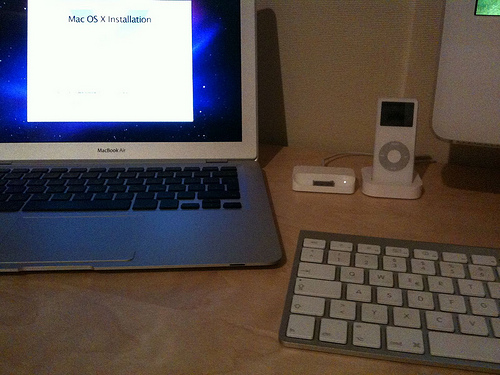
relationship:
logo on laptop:
[87, 139, 125, 164] [32, 33, 263, 260]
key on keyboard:
[321, 266, 424, 328] [305, 235, 484, 351]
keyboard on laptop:
[305, 235, 484, 351] [32, 33, 263, 260]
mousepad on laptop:
[26, 212, 136, 247] [32, 33, 263, 260]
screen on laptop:
[23, 47, 202, 122] [32, 33, 263, 260]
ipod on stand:
[367, 81, 417, 197] [359, 167, 421, 199]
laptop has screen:
[32, 33, 263, 260] [23, 47, 202, 122]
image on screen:
[26, 0, 195, 122] [33, 46, 309, 144]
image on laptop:
[17, 16, 260, 73] [32, 33, 263, 260]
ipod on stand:
[367, 81, 417, 197] [359, 167, 417, 195]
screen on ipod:
[23, 47, 202, 122] [367, 81, 417, 197]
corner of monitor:
[430, 75, 460, 139] [430, 27, 499, 169]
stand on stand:
[359, 167, 421, 199] [359, 167, 417, 195]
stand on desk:
[359, 167, 421, 199] [140, 285, 238, 347]